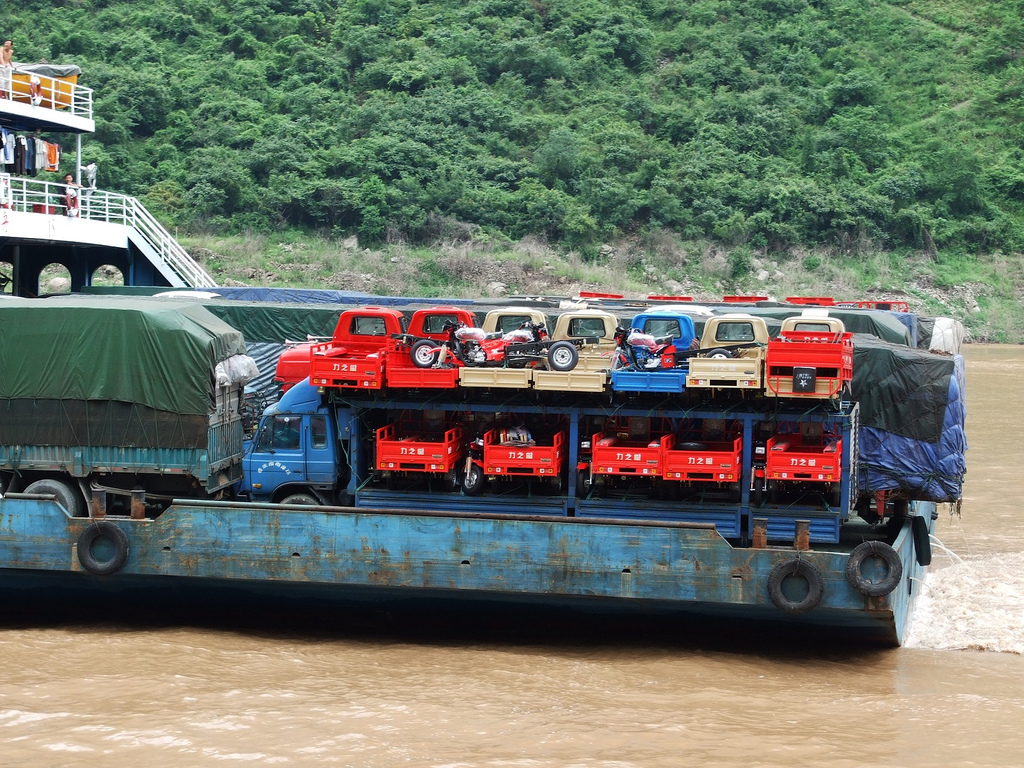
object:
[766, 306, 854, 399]
truck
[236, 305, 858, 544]
truck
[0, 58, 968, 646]
ship